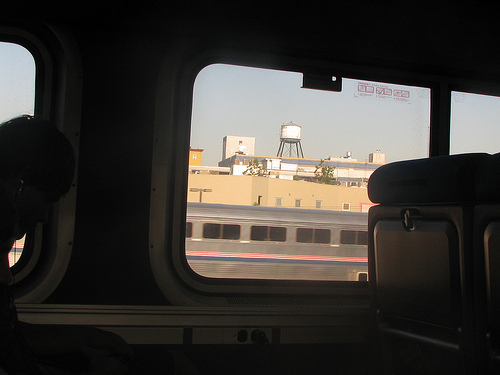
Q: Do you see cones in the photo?
A: No, there are no cones.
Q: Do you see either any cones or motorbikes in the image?
A: No, there are no cones or motorbikes.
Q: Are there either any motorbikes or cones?
A: No, there are no cones or motorbikes.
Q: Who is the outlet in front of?
A: The outlet is in front of the passenger.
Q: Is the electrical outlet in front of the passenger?
A: Yes, the electrical outlet is in front of the passenger.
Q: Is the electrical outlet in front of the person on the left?
A: Yes, the electrical outlet is in front of the passenger.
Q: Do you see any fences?
A: No, there are no fences.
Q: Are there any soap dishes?
A: No, there are no soap dishes.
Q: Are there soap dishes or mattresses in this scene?
A: No, there are no soap dishes or mattresses.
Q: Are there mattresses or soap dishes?
A: No, there are no soap dishes or mattresses.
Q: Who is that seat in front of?
A: The seat is in front of the passenger.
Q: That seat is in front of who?
A: The seat is in front of the passenger.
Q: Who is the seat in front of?
A: The seat is in front of the passenger.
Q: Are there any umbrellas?
A: No, there are no umbrellas.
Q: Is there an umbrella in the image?
A: No, there are no umbrellas.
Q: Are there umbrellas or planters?
A: No, there are no umbrellas or planters.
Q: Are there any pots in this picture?
A: No, there are no pots.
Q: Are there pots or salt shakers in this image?
A: No, there are no pots or salt shakers.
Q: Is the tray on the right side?
A: Yes, the tray is on the right of the image.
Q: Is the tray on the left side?
A: No, the tray is on the right of the image.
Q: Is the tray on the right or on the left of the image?
A: The tray is on the right of the image.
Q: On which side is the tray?
A: The tray is on the right of the image.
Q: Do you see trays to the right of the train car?
A: Yes, there is a tray to the right of the train car.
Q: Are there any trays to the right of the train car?
A: Yes, there is a tray to the right of the train car.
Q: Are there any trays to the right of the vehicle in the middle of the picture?
A: Yes, there is a tray to the right of the train car.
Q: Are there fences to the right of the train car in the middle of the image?
A: No, there is a tray to the right of the train car.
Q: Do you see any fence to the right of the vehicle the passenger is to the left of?
A: No, there is a tray to the right of the train car.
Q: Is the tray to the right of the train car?
A: Yes, the tray is to the right of the train car.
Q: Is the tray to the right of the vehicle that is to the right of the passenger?
A: Yes, the tray is to the right of the train car.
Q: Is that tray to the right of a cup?
A: No, the tray is to the right of the train car.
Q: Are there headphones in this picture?
A: Yes, there are headphones.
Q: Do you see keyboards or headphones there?
A: Yes, there are headphones.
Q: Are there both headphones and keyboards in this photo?
A: No, there are headphones but no keyboards.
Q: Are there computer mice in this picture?
A: No, there are no computer mice.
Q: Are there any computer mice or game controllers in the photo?
A: No, there are no computer mice or game controllers.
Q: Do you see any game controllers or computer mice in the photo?
A: No, there are no computer mice or game controllers.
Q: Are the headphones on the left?
A: Yes, the headphones are on the left of the image.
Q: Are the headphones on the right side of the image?
A: No, the headphones are on the left of the image.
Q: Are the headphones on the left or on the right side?
A: The headphones are on the left of the image.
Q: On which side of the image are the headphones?
A: The headphones are on the left of the image.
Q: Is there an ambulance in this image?
A: No, there are no ambulances.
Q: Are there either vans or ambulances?
A: No, there are no ambulances or vans.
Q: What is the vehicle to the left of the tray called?
A: The vehicle is a train car.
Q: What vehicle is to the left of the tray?
A: The vehicle is a train car.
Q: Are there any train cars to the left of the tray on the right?
A: Yes, there is a train car to the left of the tray.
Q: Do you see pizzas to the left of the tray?
A: No, there is a train car to the left of the tray.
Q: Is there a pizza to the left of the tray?
A: No, there is a train car to the left of the tray.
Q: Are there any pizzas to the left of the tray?
A: No, there is a train car to the left of the tray.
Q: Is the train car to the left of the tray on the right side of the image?
A: Yes, the train car is to the left of the tray.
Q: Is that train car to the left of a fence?
A: No, the train car is to the left of the tray.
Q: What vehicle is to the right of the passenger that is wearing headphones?
A: The vehicle is a train car.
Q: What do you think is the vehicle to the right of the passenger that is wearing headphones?
A: The vehicle is a train car.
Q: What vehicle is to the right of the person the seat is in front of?
A: The vehicle is a train car.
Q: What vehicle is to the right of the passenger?
A: The vehicle is a train car.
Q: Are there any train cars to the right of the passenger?
A: Yes, there is a train car to the right of the passenger.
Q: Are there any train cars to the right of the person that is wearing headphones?
A: Yes, there is a train car to the right of the passenger.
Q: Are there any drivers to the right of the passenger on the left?
A: No, there is a train car to the right of the passenger.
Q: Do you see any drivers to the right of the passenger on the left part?
A: No, there is a train car to the right of the passenger.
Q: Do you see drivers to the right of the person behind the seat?
A: No, there is a train car to the right of the passenger.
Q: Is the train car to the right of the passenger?
A: Yes, the train car is to the right of the passenger.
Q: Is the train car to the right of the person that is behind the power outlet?
A: Yes, the train car is to the right of the passenger.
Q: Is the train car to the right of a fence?
A: No, the train car is to the right of the passenger.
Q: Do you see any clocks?
A: No, there are no clocks.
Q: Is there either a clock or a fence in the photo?
A: No, there are no clocks or fences.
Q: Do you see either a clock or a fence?
A: No, there are no clocks or fences.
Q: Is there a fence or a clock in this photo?
A: No, there are no clocks or fences.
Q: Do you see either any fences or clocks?
A: No, there are no clocks or fences.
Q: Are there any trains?
A: Yes, there is a train.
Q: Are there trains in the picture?
A: Yes, there is a train.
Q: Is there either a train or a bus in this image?
A: Yes, there is a train.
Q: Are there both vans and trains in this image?
A: No, there is a train but no vans.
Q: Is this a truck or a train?
A: This is a train.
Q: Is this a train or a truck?
A: This is a train.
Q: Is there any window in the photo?
A: Yes, there is a window.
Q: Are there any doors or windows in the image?
A: Yes, there is a window.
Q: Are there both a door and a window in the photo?
A: No, there is a window but no doors.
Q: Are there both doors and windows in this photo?
A: No, there is a window but no doors.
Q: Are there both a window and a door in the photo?
A: No, there is a window but no doors.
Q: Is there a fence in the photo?
A: No, there are no fences.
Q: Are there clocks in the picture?
A: No, there are no clocks.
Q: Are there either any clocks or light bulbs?
A: No, there are no clocks or light bulbs.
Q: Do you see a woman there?
A: No, there are no women.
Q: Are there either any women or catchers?
A: No, there are no women or catchers.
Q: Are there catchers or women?
A: No, there are no women or catchers.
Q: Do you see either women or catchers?
A: No, there are no women or catchers.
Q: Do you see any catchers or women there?
A: No, there are no women or catchers.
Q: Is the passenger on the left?
A: Yes, the passenger is on the left of the image.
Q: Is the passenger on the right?
A: No, the passenger is on the left of the image.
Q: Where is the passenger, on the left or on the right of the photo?
A: The passenger is on the left of the image.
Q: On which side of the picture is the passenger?
A: The passenger is on the left of the image.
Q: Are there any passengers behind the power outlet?
A: Yes, there is a passenger behind the power outlet.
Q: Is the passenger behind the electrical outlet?
A: Yes, the passenger is behind the electrical outlet.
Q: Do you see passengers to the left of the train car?
A: Yes, there is a passenger to the left of the train car.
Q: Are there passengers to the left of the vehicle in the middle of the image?
A: Yes, there is a passenger to the left of the train car.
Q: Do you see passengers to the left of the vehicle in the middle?
A: Yes, there is a passenger to the left of the train car.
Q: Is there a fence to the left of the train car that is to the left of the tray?
A: No, there is a passenger to the left of the train car.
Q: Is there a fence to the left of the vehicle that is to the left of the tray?
A: No, there is a passenger to the left of the train car.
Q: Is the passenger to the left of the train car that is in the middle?
A: Yes, the passenger is to the left of the train car.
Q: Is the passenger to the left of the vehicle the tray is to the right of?
A: Yes, the passenger is to the left of the train car.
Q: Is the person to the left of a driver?
A: No, the passenger is to the left of the train car.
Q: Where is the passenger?
A: The passenger is in the train.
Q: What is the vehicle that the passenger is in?
A: The vehicle is a train.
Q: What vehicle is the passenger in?
A: The passenger is in the train.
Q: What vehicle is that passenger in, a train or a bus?
A: The passenger is in a train.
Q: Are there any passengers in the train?
A: Yes, there is a passenger in the train.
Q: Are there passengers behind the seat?
A: Yes, there is a passenger behind the seat.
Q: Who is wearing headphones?
A: The passenger is wearing headphones.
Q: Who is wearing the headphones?
A: The passenger is wearing headphones.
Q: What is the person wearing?
A: The passenger is wearing headphones.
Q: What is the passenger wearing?
A: The passenger is wearing headphones.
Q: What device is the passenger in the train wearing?
A: The passenger is wearing headphones.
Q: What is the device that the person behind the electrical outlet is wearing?
A: The device is headphones.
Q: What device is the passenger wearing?
A: The passenger is wearing headphones.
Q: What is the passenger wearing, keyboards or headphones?
A: The passenger is wearing headphones.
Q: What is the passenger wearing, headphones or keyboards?
A: The passenger is wearing headphones.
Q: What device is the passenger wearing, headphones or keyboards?
A: The passenger is wearing headphones.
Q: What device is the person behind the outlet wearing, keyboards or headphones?
A: The passenger is wearing headphones.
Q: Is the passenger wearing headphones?
A: Yes, the passenger is wearing headphones.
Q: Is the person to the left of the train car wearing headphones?
A: Yes, the passenger is wearing headphones.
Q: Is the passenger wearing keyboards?
A: No, the passenger is wearing headphones.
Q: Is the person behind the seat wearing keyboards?
A: No, the passenger is wearing headphones.